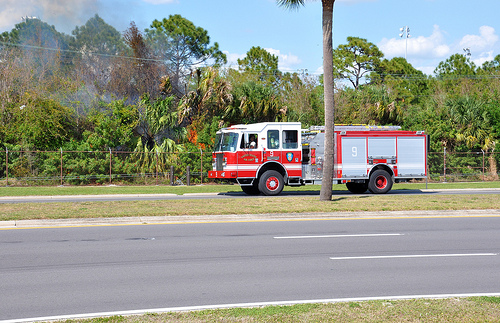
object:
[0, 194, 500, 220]
grass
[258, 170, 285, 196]
front wheel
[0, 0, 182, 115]
smoke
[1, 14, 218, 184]
field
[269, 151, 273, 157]
9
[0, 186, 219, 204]
path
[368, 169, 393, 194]
rear wheels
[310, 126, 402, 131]
ladders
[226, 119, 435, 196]
truck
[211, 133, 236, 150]
windshield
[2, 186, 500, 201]
sidewalk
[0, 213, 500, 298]
roadway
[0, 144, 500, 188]
fence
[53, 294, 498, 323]
grass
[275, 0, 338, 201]
tree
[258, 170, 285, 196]
rims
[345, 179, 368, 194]
tires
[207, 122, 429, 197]
fire engine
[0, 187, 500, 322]
road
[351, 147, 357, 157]
9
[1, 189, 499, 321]
street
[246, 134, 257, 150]
firemen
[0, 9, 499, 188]
woods